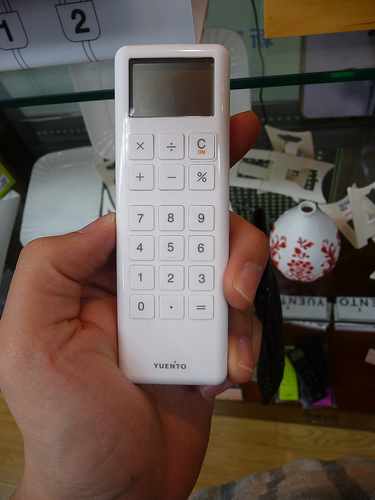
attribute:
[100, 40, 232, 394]
calculator — white, oblong, yuento, long, held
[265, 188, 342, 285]
vase — white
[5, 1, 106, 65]
letters — grey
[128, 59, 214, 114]
screen — off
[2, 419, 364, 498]
floor — wood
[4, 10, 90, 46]
numbers — grey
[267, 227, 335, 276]
print — red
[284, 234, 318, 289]
design — red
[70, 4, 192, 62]
paper — white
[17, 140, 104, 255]
plate — square, white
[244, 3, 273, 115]
cord — black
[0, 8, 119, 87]
text — grey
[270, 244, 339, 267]
patterns — floral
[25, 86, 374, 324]
desk — black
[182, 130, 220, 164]
button — white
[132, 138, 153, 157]
button — white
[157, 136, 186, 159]
button — white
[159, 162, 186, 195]
button — white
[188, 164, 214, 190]
button — white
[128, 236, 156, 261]
button — white